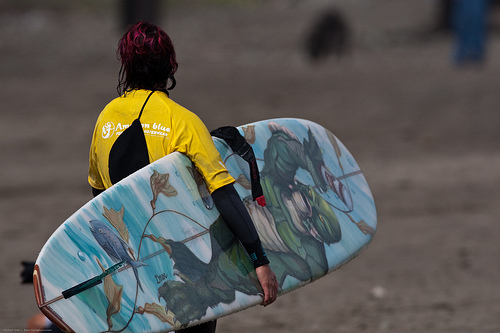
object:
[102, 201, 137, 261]
leaf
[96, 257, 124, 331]
leaf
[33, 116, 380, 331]
surfboard